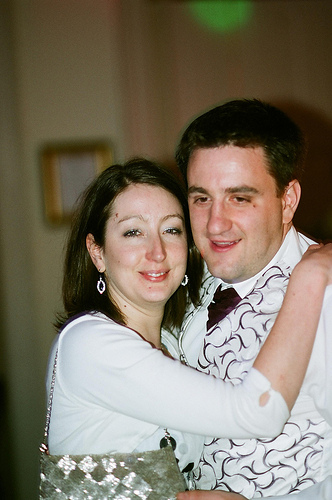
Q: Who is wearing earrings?
A: The woman.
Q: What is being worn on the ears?
A: Earrings.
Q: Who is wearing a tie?
A: The man.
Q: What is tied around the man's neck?
A: A tie.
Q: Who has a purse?
A: The woman.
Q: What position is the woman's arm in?
A: Bent.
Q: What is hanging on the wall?
A: A framed mirror.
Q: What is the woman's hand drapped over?
A: The man's shoulder.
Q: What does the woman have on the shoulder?
A: A purse.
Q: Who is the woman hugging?
A: A man.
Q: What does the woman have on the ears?
A: Ear rings.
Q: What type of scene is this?
A: Indoor.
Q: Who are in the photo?
A: People.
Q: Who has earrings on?
A: The oman.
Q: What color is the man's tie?
A: Black.